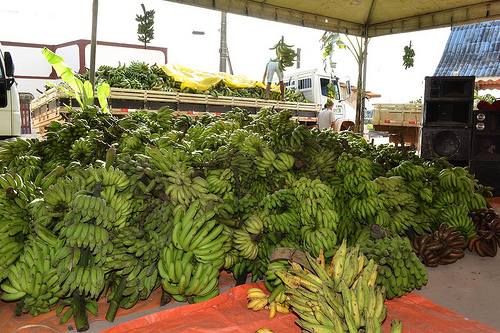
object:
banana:
[175, 271, 188, 294]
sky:
[1, 3, 445, 101]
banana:
[254, 298, 270, 312]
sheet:
[92, 276, 499, 333]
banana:
[133, 8, 158, 47]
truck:
[28, 67, 364, 138]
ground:
[408, 247, 499, 324]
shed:
[338, 80, 381, 109]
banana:
[211, 89, 218, 96]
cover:
[161, 60, 284, 93]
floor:
[0, 241, 498, 332]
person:
[314, 98, 340, 135]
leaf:
[41, 44, 88, 104]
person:
[259, 56, 287, 99]